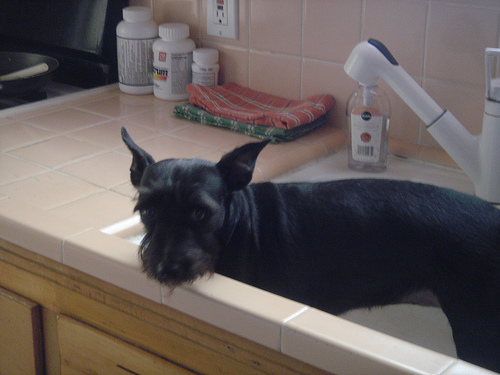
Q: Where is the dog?
A: In the sink.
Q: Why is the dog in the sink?
A: He's going to get a bath.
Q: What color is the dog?
A: Black.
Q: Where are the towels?
A: On the counter.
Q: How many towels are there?
A: Two.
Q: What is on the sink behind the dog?
A: Bottle of soap.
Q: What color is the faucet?
A: White.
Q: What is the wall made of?
A: Tile.